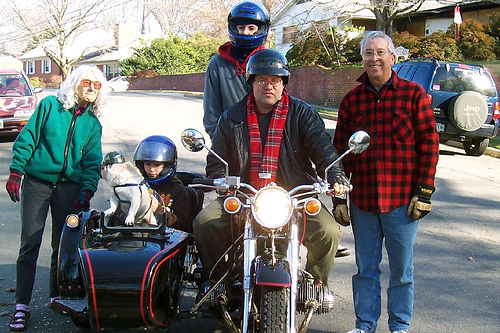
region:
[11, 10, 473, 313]
a group of people posing for a picture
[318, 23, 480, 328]
a smiling man wearing a checkered shirt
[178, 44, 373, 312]
a man on a motorcycle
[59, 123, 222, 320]
a motorcycle sidecar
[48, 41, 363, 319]
two people riding in a motorcycle and a sidecar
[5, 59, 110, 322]
an older woman in a green jacket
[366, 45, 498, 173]
an suv parked on the side of the road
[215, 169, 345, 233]
lights on a motorcycle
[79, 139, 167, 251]
a dog sitting on a sidecar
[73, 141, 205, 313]
a boy wearing a helmet in a sidecar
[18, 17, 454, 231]
people in the photo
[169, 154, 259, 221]
handlebar in the photo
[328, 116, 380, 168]
mirror in the photo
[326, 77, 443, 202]
black and red shirt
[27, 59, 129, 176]
lady in a green shirt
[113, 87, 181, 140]
light hitting the ground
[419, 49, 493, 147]
back of a car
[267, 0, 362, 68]
house near the people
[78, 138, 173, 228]
dog in the photo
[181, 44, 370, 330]
Man sitting on motorbike.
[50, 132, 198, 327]
Side car attached to motorbike.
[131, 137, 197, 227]
Young person sitting in side car.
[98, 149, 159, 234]
Dog sitting in side car with young person.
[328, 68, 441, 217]
Man dressed in red and black check shirt.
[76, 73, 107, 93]
Woman wearing sunglasses over eyes.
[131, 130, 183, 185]
Young person wearing helmet on head.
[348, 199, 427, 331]
Older man wearing blue jeans.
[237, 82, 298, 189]
Man wearing red and blue plaid scarf around neck.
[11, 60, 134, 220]
woman wearing green jacket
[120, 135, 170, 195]
boy wearing a helmet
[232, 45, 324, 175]
man wearing black jacket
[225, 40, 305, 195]
man wearing a red scarf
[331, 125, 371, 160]
mirror on a cycle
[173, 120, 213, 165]
mirror on a cycle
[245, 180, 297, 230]
light on a cycle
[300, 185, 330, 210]
light on a cycle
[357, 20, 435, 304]
man wearing a plaid shirt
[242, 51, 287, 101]
head of a person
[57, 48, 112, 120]
head of a person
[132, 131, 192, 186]
head of a person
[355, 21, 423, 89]
head of a person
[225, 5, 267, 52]
head of a person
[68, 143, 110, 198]
arm of a person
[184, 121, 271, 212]
arm of a person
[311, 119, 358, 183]
arm of a person